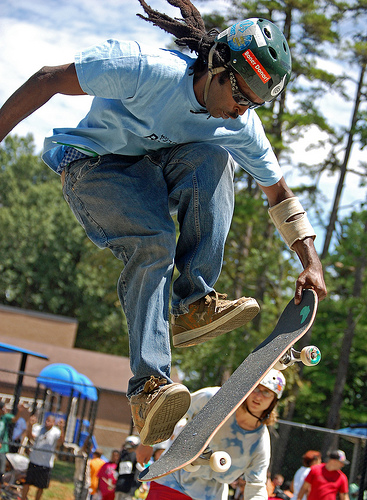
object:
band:
[267, 197, 316, 252]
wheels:
[209, 451, 231, 473]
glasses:
[230, 69, 266, 110]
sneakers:
[131, 376, 191, 446]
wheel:
[300, 345, 322, 366]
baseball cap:
[326, 449, 349, 466]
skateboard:
[137, 289, 321, 482]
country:
[300, 306, 310, 324]